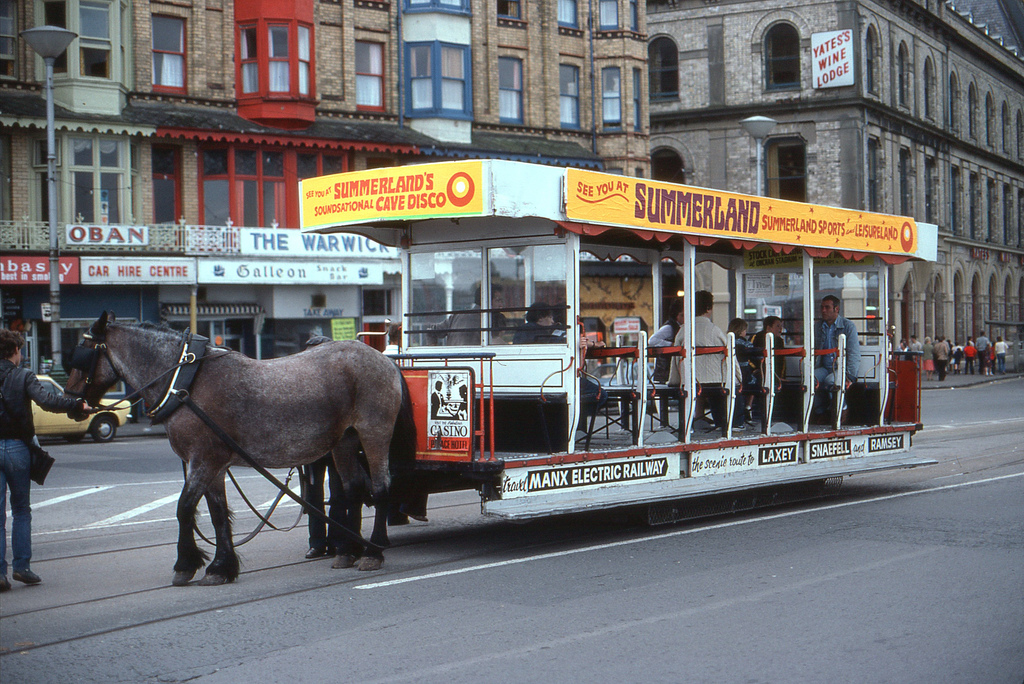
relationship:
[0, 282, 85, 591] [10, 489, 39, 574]
man has on jeans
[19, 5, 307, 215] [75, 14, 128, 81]
apartment building has a window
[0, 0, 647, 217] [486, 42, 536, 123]
apartment building has a window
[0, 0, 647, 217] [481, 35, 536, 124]
apartment building has a window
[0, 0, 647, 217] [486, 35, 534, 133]
apartment building has a window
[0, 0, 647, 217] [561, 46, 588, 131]
apartment building has a window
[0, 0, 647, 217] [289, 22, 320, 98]
apartment building has a window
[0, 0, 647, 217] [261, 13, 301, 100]
apartment building has a window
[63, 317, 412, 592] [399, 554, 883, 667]
horse standing on street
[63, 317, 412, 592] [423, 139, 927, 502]
horse pulling a trolley car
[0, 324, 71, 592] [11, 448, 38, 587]
man wearing jeans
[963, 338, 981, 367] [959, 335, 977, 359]
person wearing shirt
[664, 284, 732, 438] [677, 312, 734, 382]
woman wearing sweater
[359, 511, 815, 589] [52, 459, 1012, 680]
line painted on street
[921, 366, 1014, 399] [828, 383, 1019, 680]
curb next to street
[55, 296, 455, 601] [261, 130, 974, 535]
horse pulling trolley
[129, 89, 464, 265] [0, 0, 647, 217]
windows on apartment building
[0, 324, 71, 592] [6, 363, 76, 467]
man wearing jacket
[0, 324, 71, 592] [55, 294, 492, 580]
man guiding horse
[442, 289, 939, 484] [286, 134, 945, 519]
people sitting trolly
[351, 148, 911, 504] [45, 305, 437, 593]
trolley car being pulled by horse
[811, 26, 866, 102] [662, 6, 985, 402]
sign on building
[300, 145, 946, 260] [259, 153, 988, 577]
signs on top portion of trolley